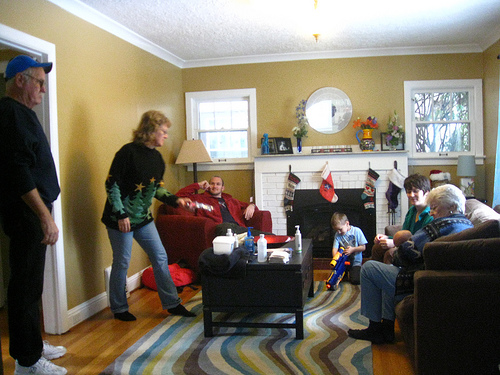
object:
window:
[404, 78, 482, 166]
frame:
[403, 79, 487, 161]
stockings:
[283, 165, 301, 213]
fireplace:
[252, 149, 405, 270]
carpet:
[105, 279, 375, 374]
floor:
[5, 267, 418, 374]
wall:
[183, 49, 487, 201]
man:
[166, 175, 276, 235]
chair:
[155, 187, 272, 285]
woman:
[97, 109, 199, 322]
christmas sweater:
[99, 141, 178, 232]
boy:
[329, 210, 369, 284]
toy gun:
[325, 246, 354, 291]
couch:
[389, 197, 500, 374]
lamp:
[174, 136, 213, 194]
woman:
[346, 183, 473, 344]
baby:
[384, 229, 414, 264]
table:
[198, 237, 315, 340]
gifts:
[210, 222, 306, 264]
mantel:
[254, 148, 408, 158]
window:
[183, 88, 257, 173]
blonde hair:
[423, 184, 467, 214]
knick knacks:
[262, 133, 271, 155]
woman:
[369, 174, 436, 261]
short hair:
[403, 173, 431, 195]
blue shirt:
[332, 225, 369, 266]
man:
[1, 51, 67, 375]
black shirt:
[0, 92, 62, 207]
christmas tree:
[107, 179, 127, 216]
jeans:
[106, 217, 183, 314]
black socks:
[15, 352, 41, 367]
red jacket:
[166, 182, 258, 229]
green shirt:
[403, 203, 433, 235]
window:
[305, 86, 353, 135]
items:
[290, 96, 310, 152]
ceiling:
[41, 0, 498, 70]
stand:
[456, 154, 479, 198]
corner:
[455, 42, 499, 199]